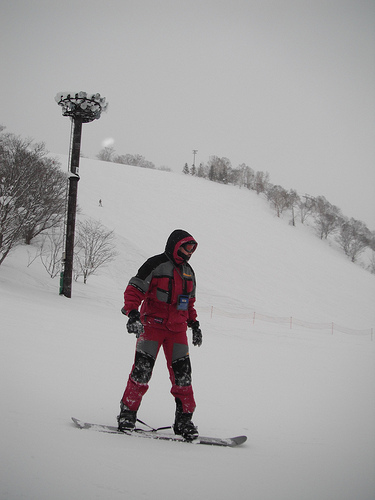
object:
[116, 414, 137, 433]
shoe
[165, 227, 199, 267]
head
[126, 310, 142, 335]
hand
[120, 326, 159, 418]
leg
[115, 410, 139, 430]
foot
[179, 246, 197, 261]
goggles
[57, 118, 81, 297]
pole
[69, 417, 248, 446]
skiboard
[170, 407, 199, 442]
boots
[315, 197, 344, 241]
trees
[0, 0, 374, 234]
sky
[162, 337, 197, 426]
legs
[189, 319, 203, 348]
gloves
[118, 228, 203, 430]
suit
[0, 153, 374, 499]
snow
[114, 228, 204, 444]
man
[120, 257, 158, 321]
arm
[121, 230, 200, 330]
coat